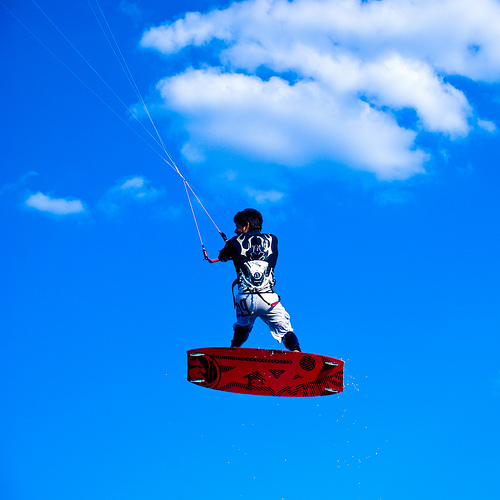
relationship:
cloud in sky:
[19, 188, 87, 222] [1, 0, 498, 498]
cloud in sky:
[151, 66, 433, 186] [1, 0, 498, 498]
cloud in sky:
[134, 2, 499, 144] [1, 0, 498, 498]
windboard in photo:
[186, 345, 345, 401] [1, 0, 498, 498]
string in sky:
[23, 2, 229, 252] [1, 0, 498, 498]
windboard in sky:
[186, 345, 345, 401] [1, 0, 498, 498]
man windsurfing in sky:
[218, 208, 303, 356] [1, 0, 498, 498]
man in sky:
[218, 208, 303, 356] [1, 0, 498, 498]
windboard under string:
[186, 345, 345, 401] [23, 2, 229, 252]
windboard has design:
[186, 345, 345, 401] [196, 353, 219, 392]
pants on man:
[233, 289, 299, 346] [218, 208, 303, 356]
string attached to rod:
[23, 2, 229, 252] [198, 232, 231, 266]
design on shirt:
[235, 234, 274, 283] [214, 233, 280, 290]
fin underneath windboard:
[190, 351, 208, 362] [186, 345, 345, 401]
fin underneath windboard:
[190, 375, 208, 387] [186, 345, 345, 401]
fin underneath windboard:
[322, 358, 341, 370] [186, 345, 345, 401]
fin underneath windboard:
[324, 384, 342, 398] [186, 345, 345, 401]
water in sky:
[315, 350, 364, 416] [1, 0, 498, 498]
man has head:
[218, 208, 303, 356] [231, 208, 266, 237]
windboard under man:
[186, 345, 345, 401] [218, 208, 303, 356]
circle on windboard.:
[297, 353, 318, 374] [186, 345, 345, 401]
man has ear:
[218, 208, 303, 356] [241, 219, 251, 235]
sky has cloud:
[1, 0, 498, 498] [19, 188, 87, 222]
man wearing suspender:
[218, 208, 303, 356] [231, 277, 282, 311]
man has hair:
[218, 208, 303, 356] [233, 209, 265, 235]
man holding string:
[218, 208, 303, 356] [23, 2, 229, 252]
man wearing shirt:
[218, 208, 303, 356] [214, 233, 280, 290]